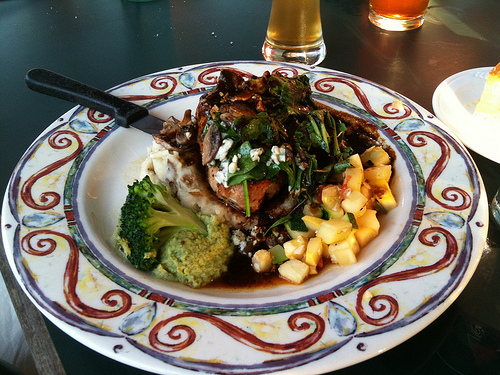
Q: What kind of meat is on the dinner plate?
A: Steak.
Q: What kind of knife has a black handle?
A: Steak.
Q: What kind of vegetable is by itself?
A: Broccoli.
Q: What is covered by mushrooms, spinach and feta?
A: A steak.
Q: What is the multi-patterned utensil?
A: A plate.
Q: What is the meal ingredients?
A: Meat and vegetables.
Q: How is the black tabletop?
A: Shiny.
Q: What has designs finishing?
A: A white plate.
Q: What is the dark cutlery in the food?
A: A knife.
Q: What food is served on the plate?
A: Brocolli.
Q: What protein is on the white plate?
A: Meat.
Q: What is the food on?
A: A plate.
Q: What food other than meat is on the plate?
A: Vegetables.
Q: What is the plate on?
A: A table.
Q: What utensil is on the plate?
A: A knife.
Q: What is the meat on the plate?
A: A steak.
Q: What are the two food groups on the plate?
A: Meat and vegetables.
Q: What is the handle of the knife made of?
A: Plastic.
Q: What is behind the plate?
A: A glass.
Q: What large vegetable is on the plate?
A: Broccoli.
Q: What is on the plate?
A: A mixture of veggies & cheese.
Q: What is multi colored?
A: The plate.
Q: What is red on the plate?
A: The scrolls on the plate.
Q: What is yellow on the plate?
A: Maybe squash.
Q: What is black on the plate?
A: Knife handle.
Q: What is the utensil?
A: A knife.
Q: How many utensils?
A: One.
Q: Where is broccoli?
A: On the plate.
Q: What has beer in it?
A: A glass.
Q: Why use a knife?
A: To cut.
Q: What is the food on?
A: A plate.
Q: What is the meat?
A: Steak.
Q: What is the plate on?
A: A table.